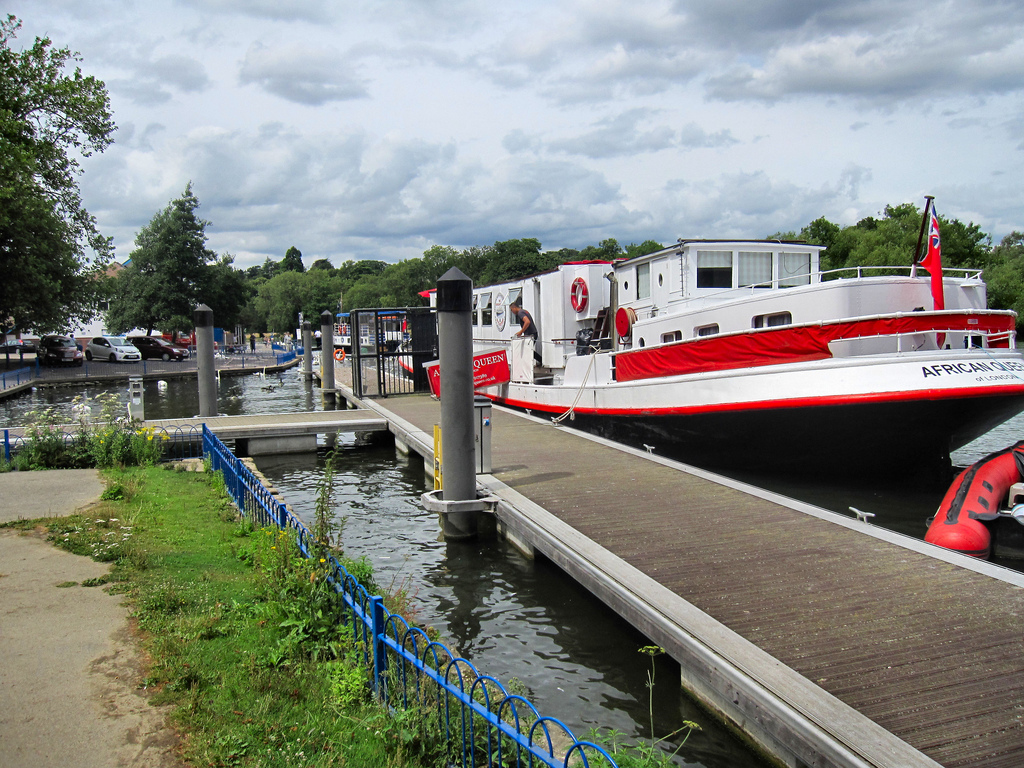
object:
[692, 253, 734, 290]
window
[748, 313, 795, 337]
window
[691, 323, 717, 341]
window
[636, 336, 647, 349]
glass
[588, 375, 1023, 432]
red trim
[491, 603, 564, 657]
water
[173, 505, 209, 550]
green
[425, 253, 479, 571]
post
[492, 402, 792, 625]
walkway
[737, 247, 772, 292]
window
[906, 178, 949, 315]
flag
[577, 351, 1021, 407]
white trim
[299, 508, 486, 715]
blue wire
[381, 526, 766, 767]
river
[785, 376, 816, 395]
white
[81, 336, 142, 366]
cars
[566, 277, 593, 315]
round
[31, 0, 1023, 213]
clouds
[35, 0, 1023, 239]
sky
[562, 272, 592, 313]
life preserver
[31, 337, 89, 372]
car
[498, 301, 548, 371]
man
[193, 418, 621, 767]
metal fence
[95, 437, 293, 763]
grass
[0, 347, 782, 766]
water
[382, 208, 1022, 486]
boat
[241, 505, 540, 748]
fence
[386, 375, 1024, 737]
dock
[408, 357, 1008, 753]
board